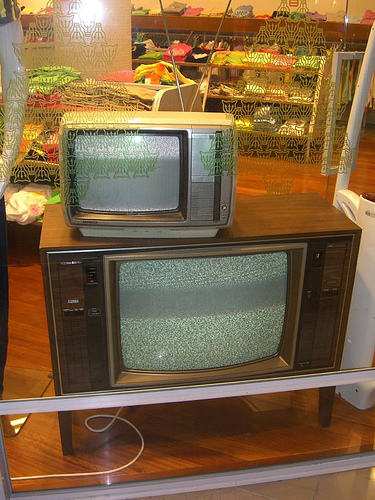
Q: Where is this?
A: This is at the store.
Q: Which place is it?
A: It is a store.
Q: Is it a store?
A: Yes, it is a store.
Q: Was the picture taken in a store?
A: Yes, it was taken in a store.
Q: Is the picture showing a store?
A: Yes, it is showing a store.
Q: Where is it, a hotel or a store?
A: It is a store.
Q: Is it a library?
A: No, it is a store.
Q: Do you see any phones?
A: No, there are no phones.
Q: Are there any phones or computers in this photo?
A: No, there are no phones or computers.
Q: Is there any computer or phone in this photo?
A: No, there are no phones or computers.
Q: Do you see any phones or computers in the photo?
A: No, there are no phones or computers.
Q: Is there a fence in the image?
A: No, there are no fences.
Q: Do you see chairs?
A: No, there are no chairs.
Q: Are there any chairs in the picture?
A: No, there are no chairs.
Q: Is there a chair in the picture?
A: No, there are no chairs.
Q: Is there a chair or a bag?
A: No, there are no chairs or bags.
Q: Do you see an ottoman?
A: No, there are no ottomen.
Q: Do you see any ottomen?
A: No, there are no ottomen.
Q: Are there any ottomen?
A: No, there are no ottomen.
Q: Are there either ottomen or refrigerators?
A: No, there are no ottomen or refrigerators.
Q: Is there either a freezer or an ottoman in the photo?
A: No, there are no ottomen or refrigerators.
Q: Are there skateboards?
A: No, there are no skateboards.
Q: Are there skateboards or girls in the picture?
A: No, there are no skateboards or girls.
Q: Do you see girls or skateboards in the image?
A: No, there are no skateboards or girls.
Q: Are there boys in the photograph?
A: No, there are no boys.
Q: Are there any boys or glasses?
A: No, there are no boys or glasses.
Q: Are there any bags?
A: No, there are no bags.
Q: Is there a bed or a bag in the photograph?
A: No, there are no bags or beds.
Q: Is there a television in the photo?
A: Yes, there is a television.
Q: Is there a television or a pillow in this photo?
A: Yes, there is a television.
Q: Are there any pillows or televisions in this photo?
A: Yes, there is a television.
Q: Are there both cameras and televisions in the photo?
A: No, there is a television but no cameras.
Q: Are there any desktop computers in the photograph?
A: No, there are no desktop computers.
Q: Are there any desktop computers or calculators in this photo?
A: No, there are no desktop computers or calculators.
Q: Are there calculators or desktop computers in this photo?
A: No, there are no desktop computers or calculators.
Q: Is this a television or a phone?
A: This is a television.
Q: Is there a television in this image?
A: Yes, there is a television.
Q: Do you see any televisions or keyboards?
A: Yes, there is a television.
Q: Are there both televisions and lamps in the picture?
A: No, there is a television but no lamps.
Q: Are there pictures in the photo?
A: No, there are no pictures.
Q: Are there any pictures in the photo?
A: No, there are no pictures.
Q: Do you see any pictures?
A: No, there are no pictures.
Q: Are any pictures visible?
A: No, there are no pictures.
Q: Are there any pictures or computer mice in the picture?
A: No, there are no pictures or computer mice.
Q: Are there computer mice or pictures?
A: No, there are no pictures or computer mice.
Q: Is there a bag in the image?
A: No, there are no bags.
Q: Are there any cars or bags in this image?
A: No, there are no bags or cars.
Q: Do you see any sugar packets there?
A: No, there are no sugar packets.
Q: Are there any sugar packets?
A: No, there are no sugar packets.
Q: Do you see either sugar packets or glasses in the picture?
A: No, there are no sugar packets or glasses.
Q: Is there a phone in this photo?
A: No, there are no phones.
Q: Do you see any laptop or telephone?
A: No, there are no phones or laptops.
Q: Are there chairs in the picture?
A: No, there are no chairs.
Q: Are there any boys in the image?
A: No, there are no boys.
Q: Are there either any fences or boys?
A: No, there are no boys or fences.